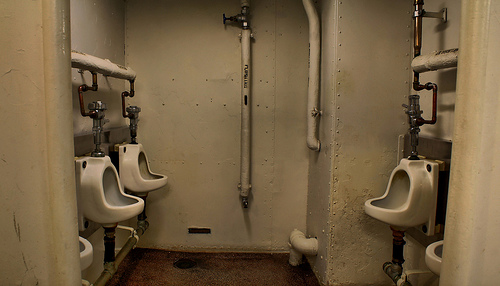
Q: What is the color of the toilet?
A: White.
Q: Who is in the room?
A: No one.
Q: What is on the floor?
A: Drainage.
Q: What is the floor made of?
A: Ceramic.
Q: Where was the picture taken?
A: Public bathroom.